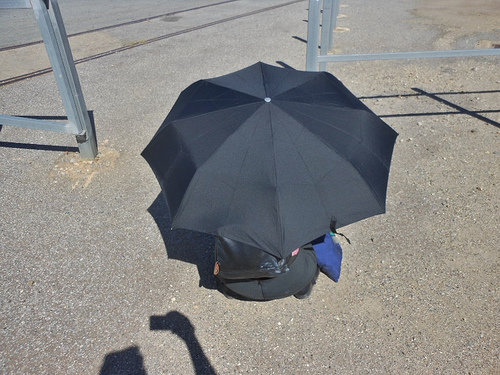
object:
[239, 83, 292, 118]
tip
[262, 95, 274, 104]
button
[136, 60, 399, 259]
umbrella